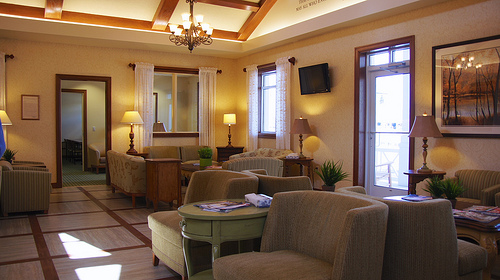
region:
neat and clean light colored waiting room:
[57, 36, 463, 253]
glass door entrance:
[345, 25, 422, 217]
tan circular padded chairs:
[220, 186, 470, 270]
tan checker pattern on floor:
[58, 181, 131, 268]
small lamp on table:
[120, 101, 142, 163]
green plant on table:
[307, 151, 358, 193]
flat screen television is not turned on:
[280, 46, 340, 113]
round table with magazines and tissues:
[170, 185, 273, 253]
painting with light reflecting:
[415, 36, 495, 141]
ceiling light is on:
[150, 11, 237, 62]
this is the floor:
[48, 229, 125, 276]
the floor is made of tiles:
[49, 218, 133, 265]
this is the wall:
[24, 40, 39, 79]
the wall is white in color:
[20, 46, 43, 85]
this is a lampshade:
[407, 114, 444, 171]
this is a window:
[260, 96, 275, 131]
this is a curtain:
[276, 91, 289, 146]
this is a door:
[370, 92, 398, 184]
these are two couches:
[293, 215, 453, 267]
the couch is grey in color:
[286, 214, 343, 278]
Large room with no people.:
[0, 14, 495, 273]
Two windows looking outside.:
[256, 50, 430, 229]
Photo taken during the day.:
[244, 48, 459, 232]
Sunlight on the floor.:
[36, 222, 118, 279]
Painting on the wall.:
[432, 27, 496, 147]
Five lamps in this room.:
[0, 93, 459, 190]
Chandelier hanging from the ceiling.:
[167, 6, 237, 53]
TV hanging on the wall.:
[298, 62, 346, 108]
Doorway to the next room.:
[22, 58, 128, 216]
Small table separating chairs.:
[168, 178, 285, 279]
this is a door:
[56, 80, 105, 184]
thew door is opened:
[65, 88, 94, 152]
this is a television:
[297, 66, 329, 92]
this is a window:
[140, 64, 212, 134]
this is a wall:
[21, 50, 44, 89]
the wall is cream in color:
[19, 50, 49, 87]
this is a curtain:
[197, 66, 217, 137]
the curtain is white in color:
[201, 73, 213, 130]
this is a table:
[183, 201, 246, 234]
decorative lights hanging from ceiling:
[167, 9, 220, 50]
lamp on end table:
[403, 110, 445, 175]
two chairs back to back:
[263, 189, 491, 278]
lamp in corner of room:
[217, 107, 244, 147]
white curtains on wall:
[129, 60, 219, 149]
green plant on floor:
[315, 152, 352, 197]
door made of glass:
[366, 68, 411, 192]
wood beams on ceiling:
[49, 0, 174, 32]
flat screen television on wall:
[294, 53, 337, 99]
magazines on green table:
[194, 191, 251, 221]